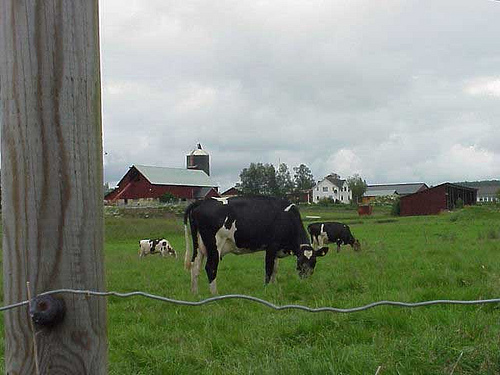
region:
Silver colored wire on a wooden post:
[13, 281, 495, 338]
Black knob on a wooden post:
[15, 278, 72, 330]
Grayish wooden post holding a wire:
[1, 2, 104, 373]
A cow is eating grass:
[181, 195, 326, 296]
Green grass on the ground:
[398, 241, 463, 284]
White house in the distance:
[303, 170, 360, 211]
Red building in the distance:
[117, 160, 215, 206]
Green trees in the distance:
[232, 160, 316, 203]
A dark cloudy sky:
[131, 10, 453, 128]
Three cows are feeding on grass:
[139, 197, 365, 290]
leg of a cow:
[205, 248, 241, 298]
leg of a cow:
[178, 239, 214, 302]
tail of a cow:
[180, 227, 203, 272]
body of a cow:
[180, 182, 305, 272]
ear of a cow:
[290, 241, 302, 253]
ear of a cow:
[316, 245, 331, 258]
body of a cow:
[306, 210, 353, 247]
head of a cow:
[165, 242, 180, 262]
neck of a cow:
[279, 202, 320, 261]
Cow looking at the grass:
[182, 195, 327, 295]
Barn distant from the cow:
[105, 149, 223, 219]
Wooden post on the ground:
[0, 1, 111, 373]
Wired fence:
[4, 278, 495, 372]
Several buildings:
[300, 169, 498, 213]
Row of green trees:
[237, 153, 314, 204]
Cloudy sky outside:
[98, 2, 496, 203]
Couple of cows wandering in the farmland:
[135, 188, 362, 299]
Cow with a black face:
[181, 188, 325, 298]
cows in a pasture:
[106, 133, 481, 335]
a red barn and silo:
[113, 128, 226, 208]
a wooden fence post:
[4, 3, 110, 368]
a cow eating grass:
[178, 192, 332, 316]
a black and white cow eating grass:
[178, 190, 338, 317]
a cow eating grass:
[130, 230, 182, 280]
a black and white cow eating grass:
[126, 225, 183, 273]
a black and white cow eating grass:
[306, 213, 381, 270]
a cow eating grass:
[308, 219, 378, 270]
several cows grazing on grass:
[121, 203, 383, 315]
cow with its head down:
[276, 228, 330, 285]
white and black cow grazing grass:
[128, 230, 180, 262]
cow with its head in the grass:
[305, 204, 371, 264]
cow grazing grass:
[165, 173, 336, 296]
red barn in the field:
[122, 148, 226, 210]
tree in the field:
[342, 175, 370, 203]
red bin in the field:
[354, 197, 377, 221]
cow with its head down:
[305, 208, 365, 265]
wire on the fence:
[36, 282, 483, 318]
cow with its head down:
[162, 183, 327, 298]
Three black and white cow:
[136, 193, 362, 299]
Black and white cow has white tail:
[181, 193, 331, 300]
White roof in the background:
[131, 163, 218, 188]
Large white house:
[305, 172, 355, 205]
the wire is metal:
[123, 282, 497, 334]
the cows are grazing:
[122, 207, 374, 285]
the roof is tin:
[139, 160, 210, 202]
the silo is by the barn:
[188, 136, 210, 175]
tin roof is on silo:
[188, 147, 201, 157]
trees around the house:
[285, 165, 355, 212]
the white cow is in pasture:
[134, 232, 181, 277]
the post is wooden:
[4, 7, 112, 349]